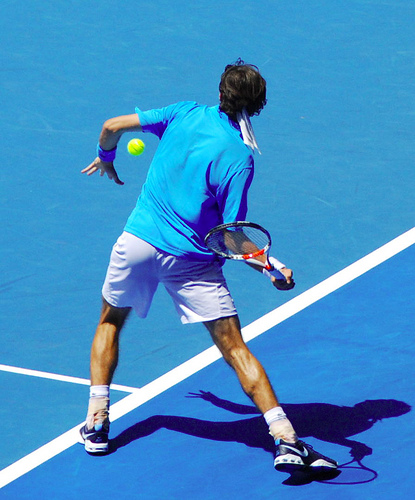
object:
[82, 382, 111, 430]
brace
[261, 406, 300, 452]
brace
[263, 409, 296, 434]
ankle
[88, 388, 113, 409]
ankle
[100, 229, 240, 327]
shorts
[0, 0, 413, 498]
tennis court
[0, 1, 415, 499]
ground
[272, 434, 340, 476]
shoe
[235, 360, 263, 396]
muscle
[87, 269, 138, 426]
leg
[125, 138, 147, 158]
tennis ball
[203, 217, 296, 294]
racquet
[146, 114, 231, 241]
back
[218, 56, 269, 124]
hair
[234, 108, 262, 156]
band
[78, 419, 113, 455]
shoe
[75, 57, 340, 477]
man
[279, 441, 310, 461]
logo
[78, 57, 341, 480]
tennis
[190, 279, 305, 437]
leg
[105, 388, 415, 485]
shadow